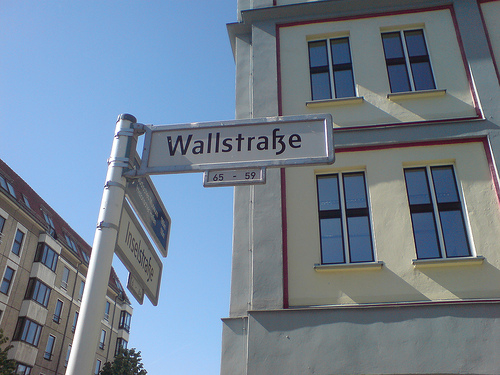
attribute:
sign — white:
[135, 113, 335, 184]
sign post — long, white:
[70, 111, 133, 361]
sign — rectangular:
[137, 116, 339, 188]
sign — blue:
[130, 178, 184, 244]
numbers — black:
[210, 167, 259, 182]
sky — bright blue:
[1, 15, 232, 373]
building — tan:
[225, 4, 499, 372]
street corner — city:
[3, 104, 375, 374]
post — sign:
[74, 116, 135, 370]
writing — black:
[169, 139, 301, 151]